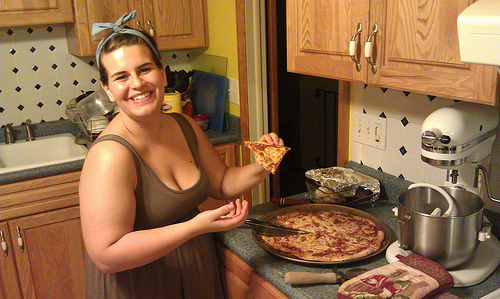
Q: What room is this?
A: Kitchen.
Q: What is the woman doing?
A: Cutting pizza.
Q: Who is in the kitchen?
A: A woman.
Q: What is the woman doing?
A: Eating pizza.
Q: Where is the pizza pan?
A: On the countertop.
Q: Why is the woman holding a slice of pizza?
A: She is eating.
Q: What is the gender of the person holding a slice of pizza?
A: Female.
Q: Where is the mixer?
A: On the counter.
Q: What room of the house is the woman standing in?
A: Kitchen.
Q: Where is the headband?
A: On the woman's head.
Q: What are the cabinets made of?
A: Wood.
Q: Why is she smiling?
A: Eating.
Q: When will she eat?
A: Now.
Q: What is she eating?
A: Pizza.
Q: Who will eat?
A: The lady.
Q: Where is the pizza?
A: On the counter.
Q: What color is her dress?
A: Brown.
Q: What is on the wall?
A: Cabinets.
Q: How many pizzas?
A: 1.